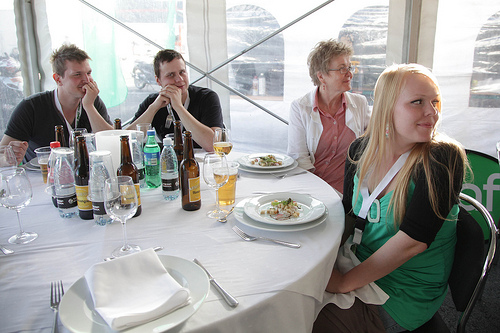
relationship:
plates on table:
[21, 148, 329, 332] [4, 154, 337, 332]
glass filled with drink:
[213, 162, 240, 206] [215, 171, 241, 205]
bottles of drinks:
[53, 119, 207, 221] [0, 117, 239, 257]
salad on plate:
[263, 196, 296, 221] [233, 190, 329, 232]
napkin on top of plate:
[82, 247, 191, 328] [59, 253, 210, 332]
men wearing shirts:
[0, 41, 115, 166] [3, 88, 109, 165]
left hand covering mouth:
[77, 83, 103, 109] [76, 83, 86, 93]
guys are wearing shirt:
[0, 44, 230, 166] [129, 87, 230, 143]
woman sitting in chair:
[316, 63, 467, 332] [411, 190, 497, 332]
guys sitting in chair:
[123, 48, 228, 153] [220, 121, 232, 135]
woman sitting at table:
[286, 35, 368, 188] [4, 154, 337, 332]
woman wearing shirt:
[316, 63, 467, 332] [337, 132, 475, 332]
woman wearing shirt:
[286, 40, 372, 190] [312, 96, 359, 188]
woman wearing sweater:
[286, 40, 372, 190] [290, 93, 370, 171]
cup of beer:
[213, 162, 240, 206] [215, 171, 241, 205]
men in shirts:
[6, 41, 240, 161] [4, 88, 227, 163]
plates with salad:
[233, 153, 329, 231] [260, 196, 304, 222]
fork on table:
[233, 223, 302, 250] [4, 154, 337, 332]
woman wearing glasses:
[286, 40, 372, 190] [323, 64, 359, 76]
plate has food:
[233, 190, 329, 232] [263, 196, 296, 221]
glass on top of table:
[213, 162, 240, 206] [4, 154, 337, 332]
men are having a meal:
[0, 44, 230, 166] [4, 144, 337, 323]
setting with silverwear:
[42, 241, 246, 332] [51, 257, 238, 314]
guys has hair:
[123, 48, 228, 153] [150, 49, 190, 78]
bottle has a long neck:
[177, 132, 204, 213] [177, 131, 200, 159]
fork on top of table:
[233, 223, 302, 250] [4, 154, 337, 332]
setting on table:
[42, 241, 246, 332] [4, 154, 337, 332]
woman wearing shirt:
[316, 63, 467, 332] [337, 132, 480, 328]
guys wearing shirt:
[123, 48, 228, 153] [139, 87, 233, 144]